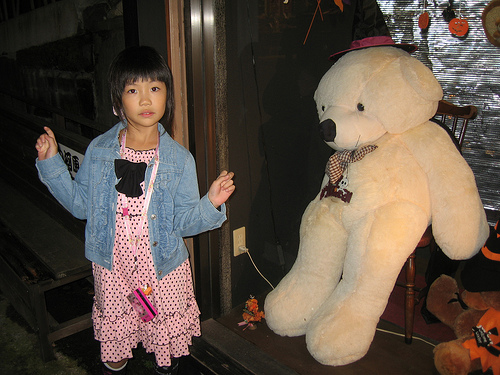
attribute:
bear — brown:
[285, 51, 456, 266]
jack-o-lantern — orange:
[445, 11, 472, 39]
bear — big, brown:
[258, 37, 480, 352]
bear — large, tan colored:
[258, 78, 451, 280]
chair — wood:
[382, 218, 435, 348]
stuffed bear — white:
[259, 6, 494, 366]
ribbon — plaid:
[260, 45, 495, 363]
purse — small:
[126, 284, 161, 329]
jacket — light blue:
[36, 127, 223, 282]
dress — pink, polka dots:
[118, 262, 205, 332]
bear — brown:
[266, 43, 479, 373]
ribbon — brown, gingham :
[324, 145, 379, 182]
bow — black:
[113, 155, 148, 197]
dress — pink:
[90, 130, 208, 367]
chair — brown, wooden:
[342, 177, 487, 360]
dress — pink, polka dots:
[63, 77, 250, 321]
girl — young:
[29, 32, 241, 373]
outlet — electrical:
[231, 224, 246, 258]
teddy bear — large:
[260, 47, 483, 357]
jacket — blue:
[35, 119, 233, 271]